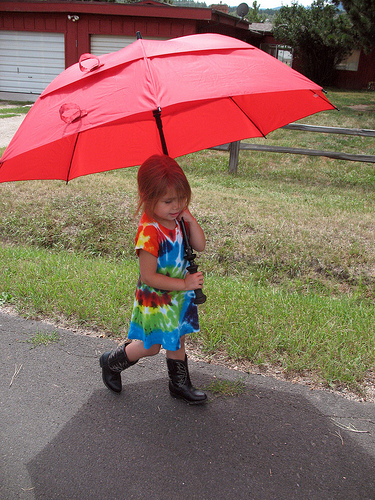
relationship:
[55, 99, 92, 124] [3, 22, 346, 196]
red loop on umbrella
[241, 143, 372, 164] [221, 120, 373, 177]
post on fence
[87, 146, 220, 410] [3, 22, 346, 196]
girl holding umbrella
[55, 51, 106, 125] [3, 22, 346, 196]
straps on umbrella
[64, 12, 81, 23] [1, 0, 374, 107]
light on building